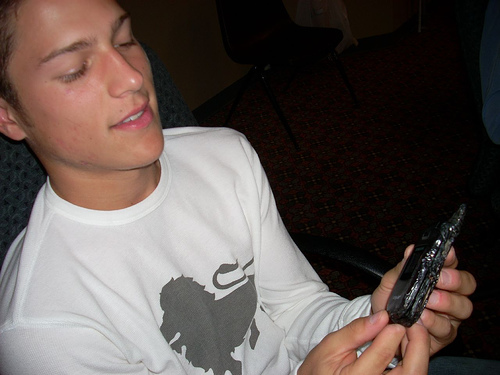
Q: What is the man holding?
A: Cell phone.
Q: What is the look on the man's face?
A: Smile.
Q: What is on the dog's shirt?
A: Lion.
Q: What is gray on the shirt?
A: A lion.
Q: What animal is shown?
A: A lion.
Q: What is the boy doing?
A: Holding something.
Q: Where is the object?
A: In the boy's hands.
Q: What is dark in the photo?
A: The background.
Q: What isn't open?
A: The man's eyes.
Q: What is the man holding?
A: Phone.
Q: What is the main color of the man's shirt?
A: White.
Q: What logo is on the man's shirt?
A: Lion.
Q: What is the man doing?
A: Smiling.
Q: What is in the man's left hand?
A: Phone.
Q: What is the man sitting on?
A: Chair.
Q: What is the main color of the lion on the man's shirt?
A: Grey.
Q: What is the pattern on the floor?
A: Geometric.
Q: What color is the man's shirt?
A: White.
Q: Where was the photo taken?
A: Baltimore.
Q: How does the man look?
A: Happy.